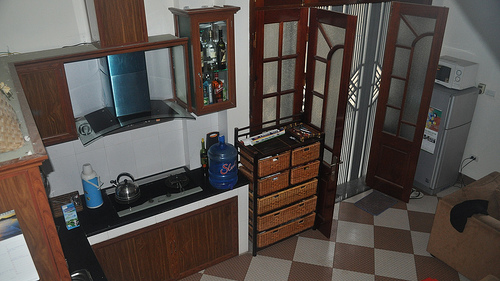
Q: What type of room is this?
A: It is a kitchen.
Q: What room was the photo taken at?
A: It was taken at the kitchen.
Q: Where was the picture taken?
A: It was taken at the kitchen.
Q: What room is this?
A: It is a kitchen.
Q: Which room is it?
A: It is a kitchen.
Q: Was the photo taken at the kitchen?
A: Yes, it was taken in the kitchen.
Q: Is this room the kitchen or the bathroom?
A: It is the kitchen.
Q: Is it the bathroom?
A: No, it is the kitchen.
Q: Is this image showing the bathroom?
A: No, the picture is showing the kitchen.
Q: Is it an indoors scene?
A: Yes, it is indoors.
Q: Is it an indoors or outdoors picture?
A: It is indoors.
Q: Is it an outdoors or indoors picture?
A: It is indoors.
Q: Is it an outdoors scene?
A: No, it is indoors.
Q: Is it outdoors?
A: No, it is indoors.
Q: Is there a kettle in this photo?
A: Yes, there is a kettle.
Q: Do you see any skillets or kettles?
A: Yes, there is a kettle.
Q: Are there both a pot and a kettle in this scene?
A: No, there is a kettle but no pots.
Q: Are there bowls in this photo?
A: No, there are no bowls.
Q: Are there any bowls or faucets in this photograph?
A: No, there are no bowls or faucets.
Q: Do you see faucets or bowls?
A: No, there are no bowls or faucets.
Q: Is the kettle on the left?
A: Yes, the kettle is on the left of the image.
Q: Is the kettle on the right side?
A: No, the kettle is on the left of the image.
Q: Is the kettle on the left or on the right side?
A: The kettle is on the left of the image.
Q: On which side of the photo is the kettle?
A: The kettle is on the left of the image.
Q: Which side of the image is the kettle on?
A: The kettle is on the left of the image.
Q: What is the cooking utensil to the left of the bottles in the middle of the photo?
A: The cooking utensil is a kettle.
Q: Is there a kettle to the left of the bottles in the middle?
A: Yes, there is a kettle to the left of the bottles.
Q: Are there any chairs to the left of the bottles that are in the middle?
A: No, there is a kettle to the left of the bottles.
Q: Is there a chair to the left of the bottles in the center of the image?
A: No, there is a kettle to the left of the bottles.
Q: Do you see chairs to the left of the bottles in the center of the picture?
A: No, there is a kettle to the left of the bottles.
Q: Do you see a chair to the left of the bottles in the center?
A: No, there is a kettle to the left of the bottles.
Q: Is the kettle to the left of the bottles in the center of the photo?
A: Yes, the kettle is to the left of the bottles.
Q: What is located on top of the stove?
A: The kettle is on top of the stove.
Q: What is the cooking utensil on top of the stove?
A: The cooking utensil is a kettle.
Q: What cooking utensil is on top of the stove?
A: The cooking utensil is a kettle.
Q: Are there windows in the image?
A: Yes, there is a window.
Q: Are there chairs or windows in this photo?
A: Yes, there is a window.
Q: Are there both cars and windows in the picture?
A: No, there is a window but no cars.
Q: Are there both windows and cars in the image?
A: No, there is a window but no cars.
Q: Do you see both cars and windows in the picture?
A: No, there is a window but no cars.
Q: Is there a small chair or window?
A: Yes, there is a small window.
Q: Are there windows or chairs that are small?
A: Yes, the window is small.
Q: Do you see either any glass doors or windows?
A: Yes, there is a glass window.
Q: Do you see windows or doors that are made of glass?
A: Yes, the window is made of glass.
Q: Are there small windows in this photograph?
A: Yes, there is a small window.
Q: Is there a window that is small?
A: Yes, there is a window that is small.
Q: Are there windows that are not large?
A: Yes, there is a small window.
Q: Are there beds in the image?
A: No, there are no beds.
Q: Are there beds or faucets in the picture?
A: No, there are no beds or faucets.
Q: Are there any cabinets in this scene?
A: Yes, there is a cabinet.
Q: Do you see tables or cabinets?
A: Yes, there is a cabinet.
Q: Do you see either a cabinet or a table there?
A: Yes, there is a cabinet.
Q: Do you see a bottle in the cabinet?
A: Yes, there are bottles in the cabinet.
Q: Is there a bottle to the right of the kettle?
A: Yes, there are bottles to the right of the kettle.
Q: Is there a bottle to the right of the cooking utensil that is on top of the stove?
A: Yes, there are bottles to the right of the kettle.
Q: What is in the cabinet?
A: The bottles are in the cabinet.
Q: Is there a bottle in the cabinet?
A: Yes, there are bottles in the cabinet.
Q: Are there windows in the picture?
A: Yes, there is a window.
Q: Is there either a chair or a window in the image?
A: Yes, there is a window.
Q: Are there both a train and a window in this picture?
A: No, there is a window but no trains.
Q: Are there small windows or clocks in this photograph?
A: Yes, there is a small window.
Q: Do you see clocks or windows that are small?
A: Yes, the window is small.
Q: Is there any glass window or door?
A: Yes, there is a glass window.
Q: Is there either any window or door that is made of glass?
A: Yes, the window is made of glass.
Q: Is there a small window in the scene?
A: Yes, there is a small window.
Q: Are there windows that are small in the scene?
A: Yes, there is a small window.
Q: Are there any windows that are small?
A: Yes, there is a window that is small.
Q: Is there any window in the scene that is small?
A: Yes, there is a window that is small.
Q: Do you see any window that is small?
A: Yes, there is a window that is small.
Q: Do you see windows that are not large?
A: Yes, there is a small window.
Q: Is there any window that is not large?
A: Yes, there is a small window.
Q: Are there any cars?
A: No, there are no cars.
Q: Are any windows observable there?
A: Yes, there is a window.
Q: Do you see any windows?
A: Yes, there is a window.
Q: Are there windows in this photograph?
A: Yes, there is a window.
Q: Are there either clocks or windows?
A: Yes, there is a window.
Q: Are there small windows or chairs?
A: Yes, there is a small window.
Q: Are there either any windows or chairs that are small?
A: Yes, the window is small.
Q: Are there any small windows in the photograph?
A: Yes, there is a small window.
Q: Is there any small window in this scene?
A: Yes, there is a small window.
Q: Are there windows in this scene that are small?
A: Yes, there is a window that is small.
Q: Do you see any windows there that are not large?
A: Yes, there is a small window.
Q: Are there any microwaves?
A: Yes, there is a microwave.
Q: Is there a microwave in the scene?
A: Yes, there is a microwave.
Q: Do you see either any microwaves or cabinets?
A: Yes, there is a microwave.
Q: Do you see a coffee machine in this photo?
A: No, there are no coffee makers.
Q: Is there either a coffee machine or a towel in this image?
A: No, there are no coffee makers or towels.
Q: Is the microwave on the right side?
A: Yes, the microwave is on the right of the image.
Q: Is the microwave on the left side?
A: No, the microwave is on the right of the image.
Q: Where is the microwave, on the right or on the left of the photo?
A: The microwave is on the right of the image.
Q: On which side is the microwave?
A: The microwave is on the right of the image.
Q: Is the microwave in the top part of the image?
A: Yes, the microwave is in the top of the image.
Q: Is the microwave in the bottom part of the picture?
A: No, the microwave is in the top of the image.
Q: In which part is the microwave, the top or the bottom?
A: The microwave is in the top of the image.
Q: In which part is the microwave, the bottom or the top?
A: The microwave is in the top of the image.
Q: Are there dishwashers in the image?
A: No, there are no dishwashers.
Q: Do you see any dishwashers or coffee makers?
A: No, there are no dishwashers or coffee makers.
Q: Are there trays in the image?
A: No, there are no trays.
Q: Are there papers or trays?
A: No, there are no trays or papers.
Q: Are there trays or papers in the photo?
A: No, there are no trays or papers.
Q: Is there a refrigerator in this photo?
A: Yes, there is a refrigerator.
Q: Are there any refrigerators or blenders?
A: Yes, there is a refrigerator.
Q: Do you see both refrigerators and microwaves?
A: Yes, there are both a refrigerator and a microwave.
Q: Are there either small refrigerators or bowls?
A: Yes, there is a small refrigerator.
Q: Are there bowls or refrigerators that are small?
A: Yes, the refrigerator is small.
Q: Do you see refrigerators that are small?
A: Yes, there is a small refrigerator.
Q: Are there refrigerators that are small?
A: Yes, there is a refrigerator that is small.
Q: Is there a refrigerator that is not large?
A: Yes, there is a small refrigerator.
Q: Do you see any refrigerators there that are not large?
A: Yes, there is a small refrigerator.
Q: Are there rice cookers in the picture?
A: No, there are no rice cookers.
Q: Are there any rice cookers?
A: No, there are no rice cookers.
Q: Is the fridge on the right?
A: Yes, the fridge is on the right of the image.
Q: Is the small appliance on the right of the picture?
A: Yes, the fridge is on the right of the image.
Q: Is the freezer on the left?
A: No, the freezer is on the right of the image.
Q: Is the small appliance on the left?
A: No, the freezer is on the right of the image.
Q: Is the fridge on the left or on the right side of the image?
A: The fridge is on the right of the image.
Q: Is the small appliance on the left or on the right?
A: The fridge is on the right of the image.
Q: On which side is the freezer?
A: The freezer is on the right of the image.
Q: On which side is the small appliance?
A: The freezer is on the right of the image.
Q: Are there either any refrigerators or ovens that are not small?
A: No, there is a refrigerator but it is small.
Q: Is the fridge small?
A: Yes, the fridge is small.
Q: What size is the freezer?
A: The freezer is small.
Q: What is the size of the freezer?
A: The freezer is small.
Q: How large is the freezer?
A: The freezer is small.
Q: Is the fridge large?
A: No, the fridge is small.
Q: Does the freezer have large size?
A: No, the freezer is small.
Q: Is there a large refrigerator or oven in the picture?
A: No, there is a refrigerator but it is small.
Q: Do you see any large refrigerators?
A: No, there is a refrigerator but it is small.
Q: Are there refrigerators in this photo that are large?
A: No, there is a refrigerator but it is small.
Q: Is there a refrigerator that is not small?
A: No, there is a refrigerator but it is small.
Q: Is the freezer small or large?
A: The freezer is small.